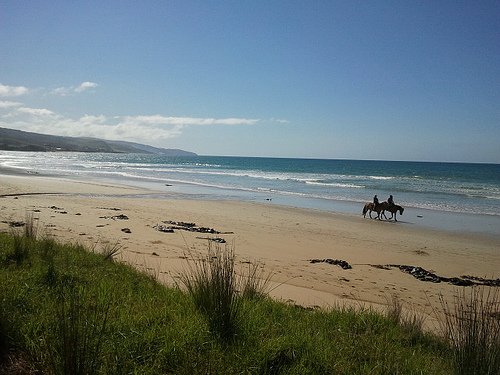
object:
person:
[371, 194, 381, 211]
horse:
[360, 194, 384, 221]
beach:
[0, 173, 495, 334]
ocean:
[6, 153, 500, 217]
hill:
[0, 127, 201, 160]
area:
[3, 227, 500, 370]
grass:
[174, 233, 296, 345]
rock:
[153, 217, 228, 241]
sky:
[1, 2, 500, 165]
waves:
[86, 156, 398, 183]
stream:
[21, 187, 254, 205]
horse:
[378, 201, 406, 223]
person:
[385, 194, 397, 205]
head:
[384, 191, 392, 196]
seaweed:
[306, 255, 355, 273]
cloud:
[0, 77, 278, 146]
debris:
[163, 180, 176, 189]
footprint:
[369, 278, 378, 287]